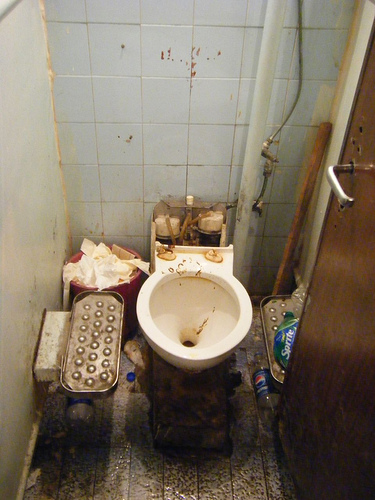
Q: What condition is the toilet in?
A: Dirty.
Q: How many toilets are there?
A: One.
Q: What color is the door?
A: Brown.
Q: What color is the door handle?
A: Silver.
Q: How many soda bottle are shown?
A: Three.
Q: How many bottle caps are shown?
A: One.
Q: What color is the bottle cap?
A: Blue.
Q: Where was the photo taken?
A: Dirty bathroom.